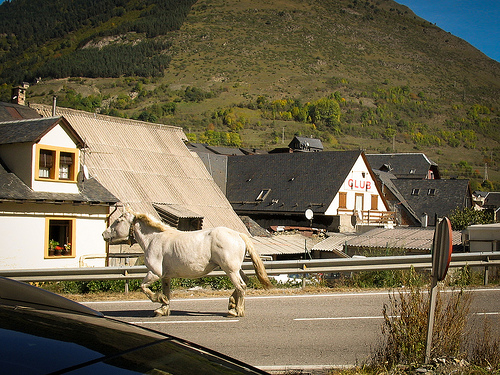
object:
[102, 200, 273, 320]
pony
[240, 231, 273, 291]
tail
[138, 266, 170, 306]
leg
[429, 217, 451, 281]
sign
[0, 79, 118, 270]
building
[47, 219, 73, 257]
window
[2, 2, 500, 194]
mountain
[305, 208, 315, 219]
dish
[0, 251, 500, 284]
railing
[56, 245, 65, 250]
plant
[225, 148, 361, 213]
roof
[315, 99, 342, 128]
tree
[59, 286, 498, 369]
road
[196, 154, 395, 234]
house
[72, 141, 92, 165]
chimney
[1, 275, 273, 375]
car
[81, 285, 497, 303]
line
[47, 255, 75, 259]
sill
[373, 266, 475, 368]
bush